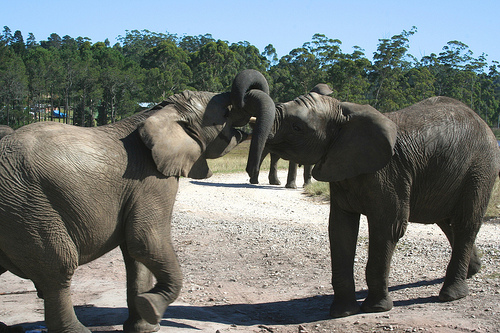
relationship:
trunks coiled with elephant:
[221, 62, 288, 194] [248, 87, 498, 308]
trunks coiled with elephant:
[221, 62, 288, 194] [1, 108, 226, 330]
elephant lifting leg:
[256, 57, 496, 324] [129, 226, 194, 323]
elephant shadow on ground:
[191, 295, 331, 332] [220, 257, 323, 292]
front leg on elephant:
[366, 204, 408, 306] [230, 68, 497, 315]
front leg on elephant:
[327, 206, 360, 311] [230, 68, 497, 315]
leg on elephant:
[251, 152, 263, 189] [254, 101, 326, 196]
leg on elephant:
[268, 145, 281, 191] [254, 101, 326, 196]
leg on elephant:
[286, 156, 299, 190] [254, 101, 326, 196]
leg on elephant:
[307, 166, 311, 193] [254, 101, 326, 196]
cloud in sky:
[0, 0, 500, 35] [14, 4, 484, 64]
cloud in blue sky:
[0, 0, 500, 35] [1, 0, 498, 88]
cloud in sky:
[0, 0, 500, 35] [1, 2, 499, 76]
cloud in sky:
[0, 0, 500, 35] [322, 14, 364, 36]